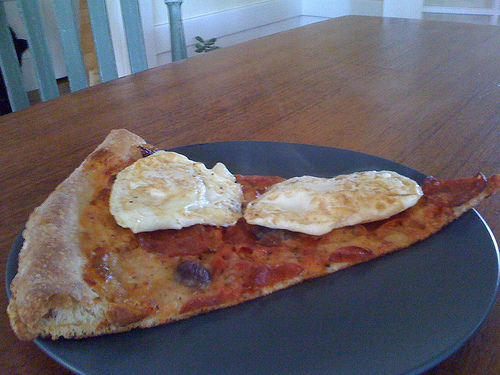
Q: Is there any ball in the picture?
A: No, there are no balls.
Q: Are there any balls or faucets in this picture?
A: No, there are no balls or faucets.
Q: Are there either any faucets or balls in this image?
A: No, there are no balls or faucets.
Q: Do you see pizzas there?
A: Yes, there is a pizza.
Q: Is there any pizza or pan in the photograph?
A: Yes, there is a pizza.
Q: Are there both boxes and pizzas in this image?
A: No, there is a pizza but no boxes.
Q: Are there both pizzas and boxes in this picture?
A: No, there is a pizza but no boxes.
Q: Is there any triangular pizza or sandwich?
A: Yes, there is a triangular pizza.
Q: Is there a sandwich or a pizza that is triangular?
A: Yes, the pizza is triangular.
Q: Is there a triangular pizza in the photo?
A: Yes, there is a triangular pizza.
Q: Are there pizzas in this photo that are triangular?
A: Yes, there is a pizza that is triangular.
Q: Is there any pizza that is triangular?
A: Yes, there is a pizza that is triangular.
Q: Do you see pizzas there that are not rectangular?
A: Yes, there is a triangular pizza.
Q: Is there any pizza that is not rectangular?
A: Yes, there is a triangular pizza.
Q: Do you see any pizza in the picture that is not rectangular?
A: Yes, there is a triangular pizza.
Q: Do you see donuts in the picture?
A: No, there are no donuts.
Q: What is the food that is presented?
A: The food is a pizza.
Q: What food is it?
A: The food is a pizza.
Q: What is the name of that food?
A: This is a pizza.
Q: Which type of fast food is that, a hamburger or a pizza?
A: This is a pizza.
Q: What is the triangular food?
A: The food is a pizza.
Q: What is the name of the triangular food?
A: The food is a pizza.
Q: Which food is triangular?
A: The food is a pizza.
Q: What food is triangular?
A: The food is a pizza.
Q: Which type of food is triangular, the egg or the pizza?
A: The pizza is triangular.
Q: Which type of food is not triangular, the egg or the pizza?
A: The egg is not triangular.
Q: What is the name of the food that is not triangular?
A: The food is an egg.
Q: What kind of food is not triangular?
A: The food is an egg.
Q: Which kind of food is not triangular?
A: The food is an egg.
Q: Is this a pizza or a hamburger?
A: This is a pizza.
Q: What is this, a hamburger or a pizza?
A: This is a pizza.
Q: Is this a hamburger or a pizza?
A: This is a pizza.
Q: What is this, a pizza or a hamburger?
A: This is a pizza.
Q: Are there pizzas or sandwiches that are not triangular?
A: No, there is a pizza but it is triangular.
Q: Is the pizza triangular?
A: Yes, the pizza is triangular.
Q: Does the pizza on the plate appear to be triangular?
A: Yes, the pizza is triangular.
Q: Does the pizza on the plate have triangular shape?
A: Yes, the pizza is triangular.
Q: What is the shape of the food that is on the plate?
A: The pizza is triangular.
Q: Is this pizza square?
A: No, the pizza is triangular.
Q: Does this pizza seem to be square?
A: No, the pizza is triangular.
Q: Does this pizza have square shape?
A: No, the pizza is triangular.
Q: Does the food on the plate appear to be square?
A: No, the pizza is triangular.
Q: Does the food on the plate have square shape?
A: No, the pizza is triangular.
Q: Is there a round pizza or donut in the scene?
A: No, there is a pizza but it is triangular.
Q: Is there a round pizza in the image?
A: No, there is a pizza but it is triangular.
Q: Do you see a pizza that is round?
A: No, there is a pizza but it is triangular.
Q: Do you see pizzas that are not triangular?
A: No, there is a pizza but it is triangular.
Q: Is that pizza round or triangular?
A: The pizza is triangular.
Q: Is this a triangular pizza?
A: Yes, this is a triangular pizza.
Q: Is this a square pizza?
A: No, this is a triangular pizza.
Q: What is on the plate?
A: The pizza is on the plate.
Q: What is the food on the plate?
A: The food is a pizza.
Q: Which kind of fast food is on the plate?
A: The food is a pizza.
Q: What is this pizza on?
A: The pizza is on the plate.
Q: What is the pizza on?
A: The pizza is on the plate.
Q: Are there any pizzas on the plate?
A: Yes, there is a pizza on the plate.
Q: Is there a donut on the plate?
A: No, there is a pizza on the plate.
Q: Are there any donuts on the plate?
A: No, there is a pizza on the plate.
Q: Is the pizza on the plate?
A: Yes, the pizza is on the plate.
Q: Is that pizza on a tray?
A: No, the pizza is on the plate.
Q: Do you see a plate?
A: Yes, there is a plate.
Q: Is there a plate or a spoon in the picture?
A: Yes, there is a plate.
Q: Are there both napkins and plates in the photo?
A: No, there is a plate but no napkins.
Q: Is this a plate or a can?
A: This is a plate.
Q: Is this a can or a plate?
A: This is a plate.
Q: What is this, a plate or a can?
A: This is a plate.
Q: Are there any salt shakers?
A: No, there are no salt shakers.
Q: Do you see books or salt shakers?
A: No, there are no salt shakers or books.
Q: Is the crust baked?
A: Yes, the crust is baked.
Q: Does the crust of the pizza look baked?
A: Yes, the crust is baked.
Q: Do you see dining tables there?
A: Yes, there is a dining table.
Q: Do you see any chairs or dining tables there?
A: Yes, there is a dining table.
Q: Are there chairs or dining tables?
A: Yes, there is a dining table.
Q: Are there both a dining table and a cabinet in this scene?
A: No, there is a dining table but no cabinets.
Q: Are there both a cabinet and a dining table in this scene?
A: No, there is a dining table but no cabinets.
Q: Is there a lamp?
A: No, there are no lamps.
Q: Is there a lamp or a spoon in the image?
A: No, there are no lamps or spoons.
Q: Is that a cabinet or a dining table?
A: That is a dining table.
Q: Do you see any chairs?
A: Yes, there is a chair.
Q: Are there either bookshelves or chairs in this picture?
A: Yes, there is a chair.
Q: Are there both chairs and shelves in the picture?
A: No, there is a chair but no shelves.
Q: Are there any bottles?
A: No, there are no bottles.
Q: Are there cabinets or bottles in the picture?
A: No, there are no bottles or cabinets.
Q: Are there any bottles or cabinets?
A: No, there are no bottles or cabinets.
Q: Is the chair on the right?
A: No, the chair is on the left of the image.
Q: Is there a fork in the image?
A: No, there are no forks.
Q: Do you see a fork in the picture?
A: No, there are no forks.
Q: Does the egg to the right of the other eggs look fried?
A: Yes, the egg is fried.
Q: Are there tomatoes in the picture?
A: No, there are no tomatoes.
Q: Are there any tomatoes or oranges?
A: No, there are no tomatoes or oranges.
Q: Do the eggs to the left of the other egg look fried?
A: Yes, the eggs are fried.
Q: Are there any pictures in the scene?
A: No, there are no pictures.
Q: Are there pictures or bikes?
A: No, there are no pictures or bikes.